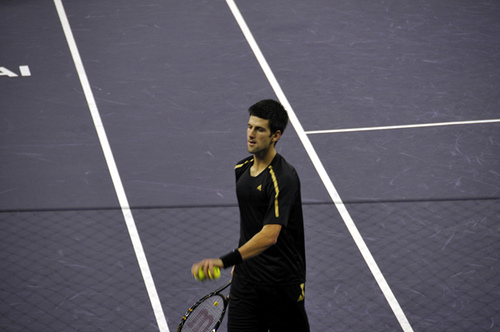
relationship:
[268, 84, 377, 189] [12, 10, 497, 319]
lines are on court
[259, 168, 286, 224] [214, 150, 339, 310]
stripe on shirt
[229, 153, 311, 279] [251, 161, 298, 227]
shirt with stripe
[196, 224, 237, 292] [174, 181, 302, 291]
balls in hand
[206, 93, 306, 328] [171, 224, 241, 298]
man holding balls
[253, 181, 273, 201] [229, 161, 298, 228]
gold logo on shirt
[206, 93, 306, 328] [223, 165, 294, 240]
man wers shirt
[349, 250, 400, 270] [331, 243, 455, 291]
white line on court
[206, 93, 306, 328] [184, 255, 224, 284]
man holding tennis ball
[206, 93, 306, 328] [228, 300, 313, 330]
man wears shorts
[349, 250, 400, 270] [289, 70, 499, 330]
white line on tennis court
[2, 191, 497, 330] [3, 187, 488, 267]
fence has shadow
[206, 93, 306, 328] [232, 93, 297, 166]
man has head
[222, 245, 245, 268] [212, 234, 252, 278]
wristband on wrist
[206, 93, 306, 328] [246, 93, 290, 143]
man has hair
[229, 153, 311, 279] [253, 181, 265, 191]
shirt has a logo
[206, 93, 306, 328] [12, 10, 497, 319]
man on court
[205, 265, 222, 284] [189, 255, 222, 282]
ball in hand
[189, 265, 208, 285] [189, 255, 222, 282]
ball in hand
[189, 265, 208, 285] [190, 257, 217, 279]
ball under fingers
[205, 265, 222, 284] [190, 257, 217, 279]
ball under fingers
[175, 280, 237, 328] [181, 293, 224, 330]
tennis racket with strings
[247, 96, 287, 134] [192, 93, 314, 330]
hair on player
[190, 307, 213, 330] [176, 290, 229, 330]
letter on racket strings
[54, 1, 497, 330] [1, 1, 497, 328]
lines on ground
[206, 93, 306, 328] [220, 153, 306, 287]
man wearing top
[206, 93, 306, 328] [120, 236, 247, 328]
man carrying racket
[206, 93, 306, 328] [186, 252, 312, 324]
man wear shorts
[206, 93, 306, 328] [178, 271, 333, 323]
man wearing shorts